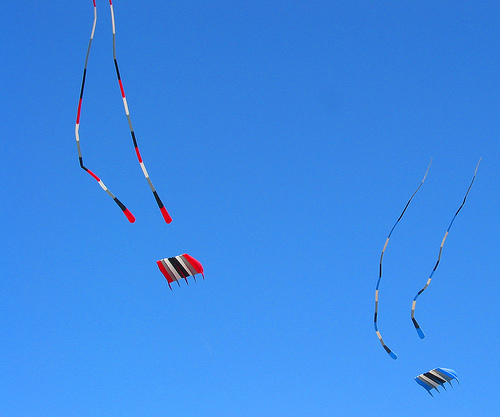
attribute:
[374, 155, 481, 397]
kite — blue, flying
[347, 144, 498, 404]
kite —  Blue, black, and white, in air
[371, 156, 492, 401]
kites —  in Group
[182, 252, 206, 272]
stripe —  Red ,  of kite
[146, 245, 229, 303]
kites — in Group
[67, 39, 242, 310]
kite — flying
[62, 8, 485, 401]
two kites —  Two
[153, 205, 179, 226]
red stripe —  first ,  red 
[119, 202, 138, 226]
red stripe — red ,  first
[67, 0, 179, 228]
kite —  red 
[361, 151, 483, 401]
kite — blue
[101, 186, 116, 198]
gray stripe —  first,  kite's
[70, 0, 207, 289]
kite tails —  kite's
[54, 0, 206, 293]
kite —  Long skinny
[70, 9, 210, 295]
kite — flying,  in Group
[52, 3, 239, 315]
kite —  in Group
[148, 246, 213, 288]
kite — red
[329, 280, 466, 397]
kite — blue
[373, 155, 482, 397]
kites —  in Group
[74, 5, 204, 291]
kites —  in Group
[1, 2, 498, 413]
sky — blue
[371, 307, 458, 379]
kite —  blue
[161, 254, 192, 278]
stripes —  White,  black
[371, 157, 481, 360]
tail — long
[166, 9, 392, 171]
sky — bright, blue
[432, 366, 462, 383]
stripes —  Blue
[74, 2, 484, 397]
kites —  in Group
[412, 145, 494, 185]
tips —  white